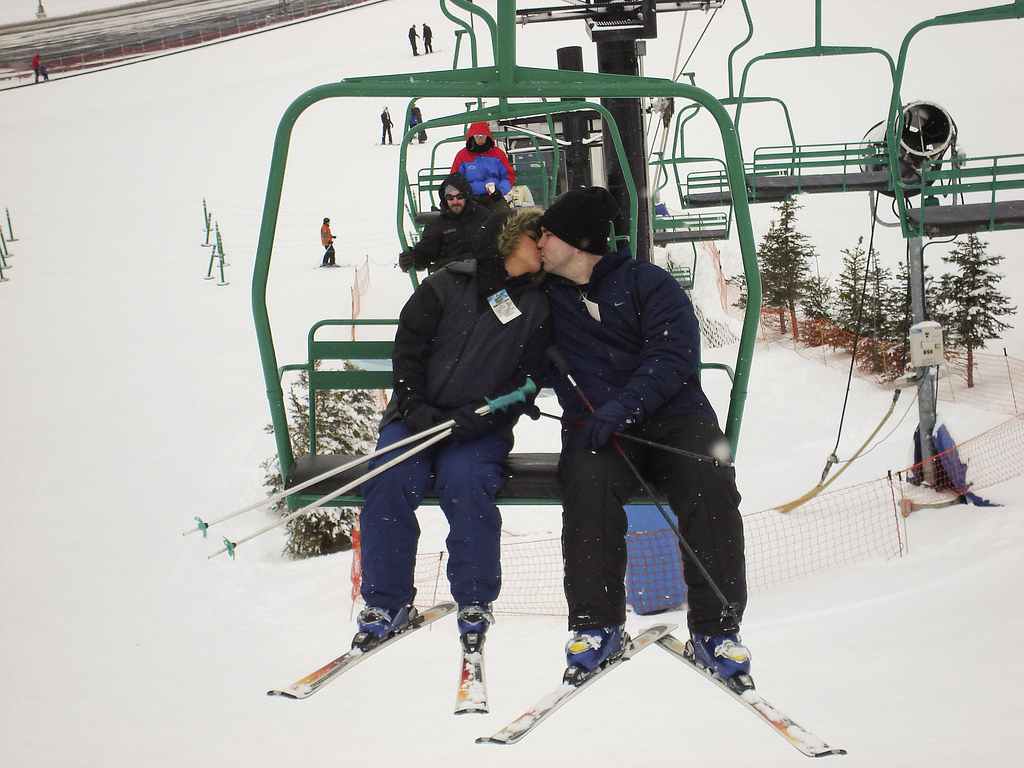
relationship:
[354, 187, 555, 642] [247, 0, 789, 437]
girl on snow lift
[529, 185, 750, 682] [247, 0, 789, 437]
guy on snow lift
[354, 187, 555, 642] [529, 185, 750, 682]
girl kissing guy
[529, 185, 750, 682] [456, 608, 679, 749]
guy wearing skis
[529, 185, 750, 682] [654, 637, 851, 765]
guy wearing skis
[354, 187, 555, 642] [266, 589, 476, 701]
girl wearing skis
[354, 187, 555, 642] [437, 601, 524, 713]
girl wearing skis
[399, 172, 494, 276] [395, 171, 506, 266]
man wearing black coat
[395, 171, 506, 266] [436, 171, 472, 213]
black coat has black hood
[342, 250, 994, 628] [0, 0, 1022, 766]
orange fence on snow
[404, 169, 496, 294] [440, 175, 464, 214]
man has face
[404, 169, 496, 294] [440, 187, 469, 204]
man has sunglasses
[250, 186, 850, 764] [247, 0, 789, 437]
couple sit in snow lift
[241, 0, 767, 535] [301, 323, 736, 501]
snow lift has bench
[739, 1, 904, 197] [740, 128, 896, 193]
snow lift has bench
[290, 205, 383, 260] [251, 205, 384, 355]
person on snow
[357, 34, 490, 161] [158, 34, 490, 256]
people on hill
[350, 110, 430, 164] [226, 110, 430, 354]
person skiing on slope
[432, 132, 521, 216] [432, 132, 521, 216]
person wearing jacket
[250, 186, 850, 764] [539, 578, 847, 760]
couple has skis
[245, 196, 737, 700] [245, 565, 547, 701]
couple has skis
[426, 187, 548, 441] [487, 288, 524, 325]
jacket has sticker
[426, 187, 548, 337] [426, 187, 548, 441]
girl has jacket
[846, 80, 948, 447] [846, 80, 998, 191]
pole has thing